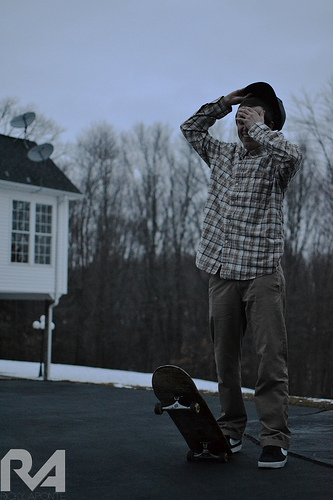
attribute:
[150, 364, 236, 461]
skateboard —  black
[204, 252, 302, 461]
pants —  A pair,  long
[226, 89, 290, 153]
head —   man's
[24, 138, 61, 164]
satellite —  two,  gray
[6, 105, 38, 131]
satellite —  gray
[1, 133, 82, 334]
house —  white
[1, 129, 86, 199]
roof —  black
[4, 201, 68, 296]
window — house's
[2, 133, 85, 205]
roof —  black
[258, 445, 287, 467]
feet —   man's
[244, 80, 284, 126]
cap —  boy's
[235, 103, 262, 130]
right hand —  boy's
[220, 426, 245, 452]
foot — the right